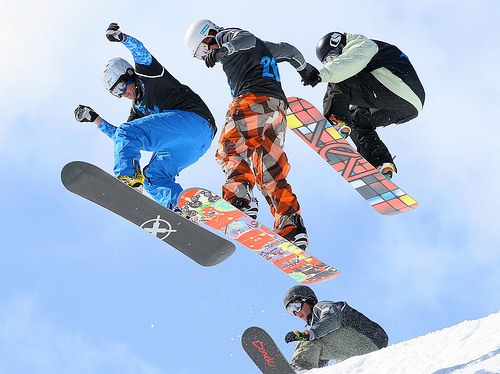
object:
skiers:
[59, 19, 424, 373]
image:
[140, 214, 177, 242]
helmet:
[183, 19, 220, 61]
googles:
[111, 79, 130, 99]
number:
[259, 53, 280, 80]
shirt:
[216, 26, 307, 107]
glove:
[203, 46, 226, 68]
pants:
[112, 109, 216, 213]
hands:
[284, 45, 368, 86]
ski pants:
[217, 92, 309, 247]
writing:
[251, 337, 274, 368]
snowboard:
[287, 96, 418, 216]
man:
[75, 21, 217, 230]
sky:
[2, 3, 490, 372]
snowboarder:
[74, 22, 216, 222]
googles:
[193, 35, 213, 59]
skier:
[183, 16, 323, 249]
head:
[101, 54, 141, 102]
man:
[182, 16, 322, 252]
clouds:
[3, 291, 163, 371]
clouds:
[278, 3, 477, 302]